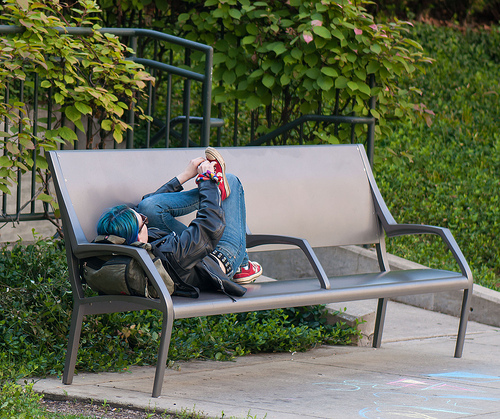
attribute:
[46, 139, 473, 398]
bench — metal, silver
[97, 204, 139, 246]
hair — blue, dyed blue, black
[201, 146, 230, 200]
shoe — converse, red, white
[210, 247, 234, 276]
belt — holey, black, silver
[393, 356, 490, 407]
chalk — colorful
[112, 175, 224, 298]
leather jacket — black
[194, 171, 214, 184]
bracelet — brightly colored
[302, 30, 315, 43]
leaf — green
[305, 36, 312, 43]
tip — pink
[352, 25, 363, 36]
leaf — green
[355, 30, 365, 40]
tip — pink